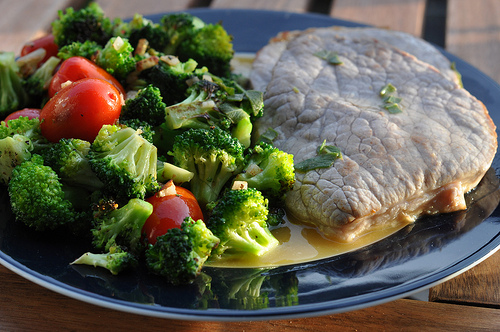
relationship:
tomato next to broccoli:
[39, 81, 122, 141] [120, 84, 165, 127]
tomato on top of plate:
[39, 81, 122, 141] [1, 9, 498, 321]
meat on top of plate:
[440, 186, 469, 216] [1, 9, 498, 321]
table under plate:
[1, 2, 499, 329] [1, 9, 498, 321]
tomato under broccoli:
[141, 183, 205, 239] [90, 126, 160, 198]